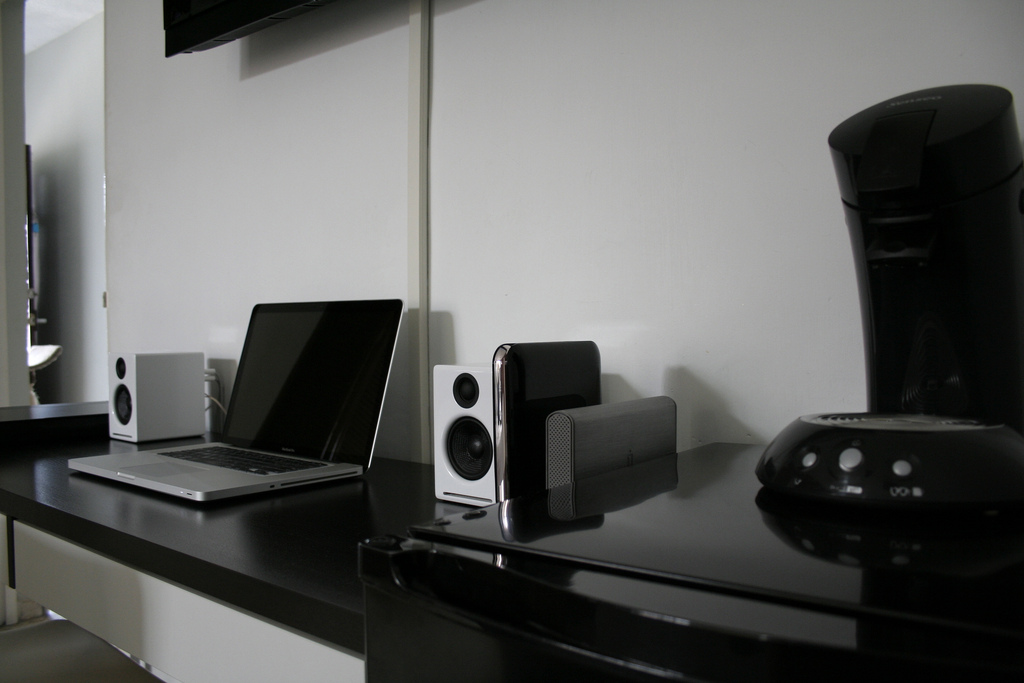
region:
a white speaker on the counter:
[106, 337, 212, 446]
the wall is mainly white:
[433, 45, 835, 340]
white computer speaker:
[428, 352, 501, 509]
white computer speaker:
[103, 346, 218, 446]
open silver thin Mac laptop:
[78, 293, 404, 508]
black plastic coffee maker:
[765, 66, 1022, 507]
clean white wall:
[103, 3, 1018, 522]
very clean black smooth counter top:
[1, 434, 486, 637]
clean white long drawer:
[4, 510, 350, 681]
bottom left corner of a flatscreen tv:
[159, 3, 445, 61]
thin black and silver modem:
[488, 331, 603, 503]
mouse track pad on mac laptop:
[114, 457, 203, 483]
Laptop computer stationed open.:
[164, 291, 409, 517]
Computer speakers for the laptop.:
[419, 364, 508, 507]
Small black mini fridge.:
[240, 505, 968, 680]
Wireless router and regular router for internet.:
[479, 325, 686, 503]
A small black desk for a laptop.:
[24, 503, 455, 653]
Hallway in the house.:
[0, 127, 102, 305]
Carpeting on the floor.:
[12, 617, 146, 675]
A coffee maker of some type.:
[752, 117, 1003, 511]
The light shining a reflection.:
[463, 496, 768, 592]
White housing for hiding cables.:
[376, 29, 501, 451]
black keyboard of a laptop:
[161, 441, 324, 479]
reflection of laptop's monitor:
[228, 302, 340, 452]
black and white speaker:
[111, 349, 187, 441]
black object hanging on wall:
[166, 1, 312, 53]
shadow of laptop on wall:
[394, 302, 442, 467]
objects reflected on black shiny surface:
[479, 481, 771, 611]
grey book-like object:
[537, 387, 684, 490]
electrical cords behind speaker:
[201, 364, 221, 451]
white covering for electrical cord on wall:
[410, 4, 436, 458]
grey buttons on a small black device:
[790, 437, 920, 483]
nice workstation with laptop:
[100, 270, 420, 566]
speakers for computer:
[391, 311, 554, 555]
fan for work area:
[697, 70, 996, 546]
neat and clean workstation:
[51, 250, 561, 675]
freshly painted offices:
[62, 59, 1023, 401]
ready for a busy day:
[28, 122, 516, 563]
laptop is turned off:
[244, 297, 377, 479]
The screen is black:
[217, 305, 395, 467]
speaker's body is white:
[81, 337, 227, 439]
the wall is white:
[100, 81, 414, 233]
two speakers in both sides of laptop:
[81, 331, 556, 468]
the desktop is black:
[42, 473, 328, 625]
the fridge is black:
[412, 511, 868, 676]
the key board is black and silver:
[74, 441, 316, 521]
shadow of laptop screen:
[397, 297, 445, 488]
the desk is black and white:
[1, 530, 164, 677]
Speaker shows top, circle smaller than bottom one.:
[428, 358, 511, 558]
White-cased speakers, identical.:
[70, 303, 507, 515]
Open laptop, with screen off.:
[76, 309, 389, 519]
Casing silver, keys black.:
[84, 323, 397, 508]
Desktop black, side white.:
[0, 462, 402, 679]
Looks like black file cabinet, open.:
[345, 527, 1017, 680]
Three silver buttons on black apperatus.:
[781, 408, 987, 522]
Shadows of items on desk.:
[380, 290, 776, 507]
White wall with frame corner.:
[105, 9, 791, 415]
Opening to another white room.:
[7, 9, 172, 447]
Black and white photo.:
[19, 24, 1022, 489]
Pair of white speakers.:
[103, 353, 533, 543]